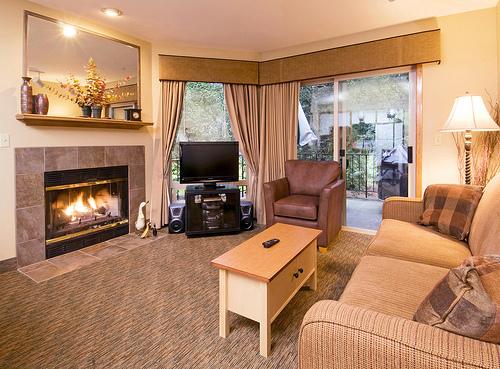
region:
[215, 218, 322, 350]
a wooden coffee table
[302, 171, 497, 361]
a brown couch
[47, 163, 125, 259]
a fire in the fireplace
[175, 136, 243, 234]
a tv on a stand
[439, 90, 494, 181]
a lamp by a couch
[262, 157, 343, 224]
a dark brown chair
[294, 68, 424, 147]
a set og sliding doors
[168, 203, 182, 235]
speckers on a floor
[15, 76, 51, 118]
vases on a shelf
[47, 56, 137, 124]
a flower in a pot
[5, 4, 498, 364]
neat and clean living room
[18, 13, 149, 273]
large mirror with shelf over fireplace and hearth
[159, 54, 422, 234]
draperies pulled open over window and door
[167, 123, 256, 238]
television set over entertainment center and speakers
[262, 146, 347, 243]
grown leather chair by glass door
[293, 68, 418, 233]
glass door showing terrace and trees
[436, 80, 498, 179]
dried grasses in back of standing lamp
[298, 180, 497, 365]
plaid pillows over woven sofa fabric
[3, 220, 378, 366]
rectagular coffee table on muted wall-to-wall carpeting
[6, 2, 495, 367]
family room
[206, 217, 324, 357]
a small table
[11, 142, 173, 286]
a fireplace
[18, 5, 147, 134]
a large mirror above the fireplace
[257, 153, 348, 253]
a chair in the room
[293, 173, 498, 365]
a sofa in the room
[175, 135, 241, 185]
a television on tv stand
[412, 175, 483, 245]
a pillow on couch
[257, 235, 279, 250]
a remote control on table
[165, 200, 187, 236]
a speaker next to tv stand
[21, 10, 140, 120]
large mirror over the fireplace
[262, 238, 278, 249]
black tv remote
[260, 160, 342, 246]
brown leather reclining chair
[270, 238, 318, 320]
storage area in the coffee table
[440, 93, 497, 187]
floor lamp with a white shade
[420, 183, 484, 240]
plaid pillow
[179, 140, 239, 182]
large flat screen tv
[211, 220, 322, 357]
wooden coffee table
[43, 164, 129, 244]
fire in the fireplace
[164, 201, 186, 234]
speaker by the entertainment center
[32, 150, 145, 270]
a fireplace with a fire in it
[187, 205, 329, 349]
a rectangular brown coffee table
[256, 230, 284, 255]
A TV remote control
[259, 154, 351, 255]
a brown leather armchair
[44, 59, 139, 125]
a potted plant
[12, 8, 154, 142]
a large mirror on the wall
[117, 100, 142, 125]
a clock on a hearth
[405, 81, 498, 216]
an ornate floor lamp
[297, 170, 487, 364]
a light brown sofa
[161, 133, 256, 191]
a TV that is turned off